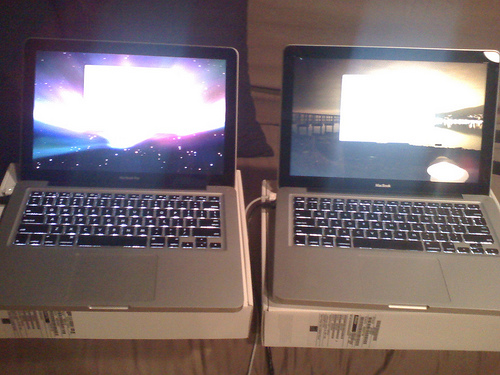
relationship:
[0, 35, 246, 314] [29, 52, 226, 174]
computer has display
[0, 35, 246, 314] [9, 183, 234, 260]
computer has keyboard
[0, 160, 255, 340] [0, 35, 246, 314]
box under computer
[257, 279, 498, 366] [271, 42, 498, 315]
box under laptop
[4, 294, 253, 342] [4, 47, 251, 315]
box under computer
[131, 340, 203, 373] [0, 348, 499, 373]
paneling on cabinet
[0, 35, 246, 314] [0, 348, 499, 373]
computer are on cabinet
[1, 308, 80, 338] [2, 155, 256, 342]
sticker on box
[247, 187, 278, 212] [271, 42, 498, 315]
cord plugged into laptop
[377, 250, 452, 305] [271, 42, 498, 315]
pad built into laptop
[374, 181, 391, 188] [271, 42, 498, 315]
brand printed on laptop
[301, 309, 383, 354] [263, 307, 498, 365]
sticker stuck on box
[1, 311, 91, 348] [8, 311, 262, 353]
sticker stuck on box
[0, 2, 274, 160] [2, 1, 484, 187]
pillow sitting in background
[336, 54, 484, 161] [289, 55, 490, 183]
white on monitor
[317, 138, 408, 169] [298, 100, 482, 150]
grey on screen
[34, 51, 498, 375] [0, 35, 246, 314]
these are two computer